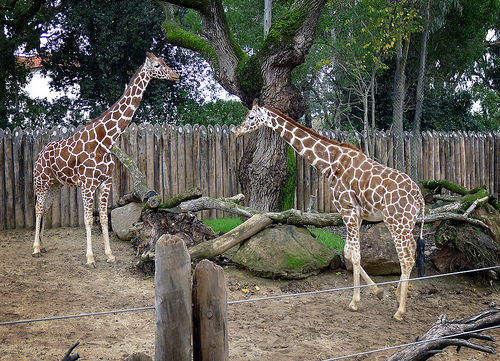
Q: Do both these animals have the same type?
A: Yes, all the animals are giraffes.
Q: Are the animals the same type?
A: Yes, all the animals are giraffes.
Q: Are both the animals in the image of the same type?
A: Yes, all the animals are giraffes.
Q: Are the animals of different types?
A: No, all the animals are giraffes.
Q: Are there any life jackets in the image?
A: No, there are no life jackets.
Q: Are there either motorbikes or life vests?
A: No, there are no life vests or motorbikes.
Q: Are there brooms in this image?
A: No, there are no brooms.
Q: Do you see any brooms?
A: No, there are no brooms.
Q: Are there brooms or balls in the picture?
A: No, there are no brooms or balls.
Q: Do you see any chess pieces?
A: No, there are no chess pieces.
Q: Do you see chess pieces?
A: No, there are no chess pieces.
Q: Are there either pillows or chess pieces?
A: No, there are no chess pieces or pillows.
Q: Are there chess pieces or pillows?
A: No, there are no chess pieces or pillows.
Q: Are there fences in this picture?
A: Yes, there is a fence.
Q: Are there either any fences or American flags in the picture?
A: Yes, there is a fence.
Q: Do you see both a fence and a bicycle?
A: No, there is a fence but no bicycles.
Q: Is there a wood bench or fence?
A: Yes, there is a wood fence.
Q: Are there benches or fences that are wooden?
A: Yes, the fence is wooden.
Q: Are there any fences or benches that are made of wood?
A: Yes, the fence is made of wood.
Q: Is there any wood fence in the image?
A: Yes, there is a fence that is made of wood.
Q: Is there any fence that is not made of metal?
A: Yes, there is a fence that is made of wood.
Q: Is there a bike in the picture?
A: No, there are no bikes.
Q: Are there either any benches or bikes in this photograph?
A: No, there are no bikes or benches.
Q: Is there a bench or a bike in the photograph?
A: No, there are no bikes or benches.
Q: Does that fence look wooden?
A: Yes, the fence is wooden.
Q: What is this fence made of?
A: The fence is made of wood.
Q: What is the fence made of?
A: The fence is made of wood.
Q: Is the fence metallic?
A: No, the fence is wooden.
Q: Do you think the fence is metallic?
A: No, the fence is wooden.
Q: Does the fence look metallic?
A: No, the fence is wooden.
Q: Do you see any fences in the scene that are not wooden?
A: No, there is a fence but it is wooden.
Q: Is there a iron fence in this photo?
A: No, there is a fence but it is made of wood.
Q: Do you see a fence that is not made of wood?
A: No, there is a fence but it is made of wood.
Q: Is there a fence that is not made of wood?
A: No, there is a fence but it is made of wood.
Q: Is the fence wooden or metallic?
A: The fence is wooden.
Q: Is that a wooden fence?
A: Yes, that is a wooden fence.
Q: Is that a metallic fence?
A: No, that is a wooden fence.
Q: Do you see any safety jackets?
A: No, there are no safety jackets.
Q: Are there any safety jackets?
A: No, there are no safety jackets.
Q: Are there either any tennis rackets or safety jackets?
A: No, there are no safety jackets or tennis rackets.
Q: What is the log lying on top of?
A: The log is lying on top of the rock.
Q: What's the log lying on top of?
A: The log is lying on top of the rock.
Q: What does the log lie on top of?
A: The log lies on top of the rock.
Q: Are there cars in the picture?
A: No, there are no cars.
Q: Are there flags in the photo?
A: No, there are no flags.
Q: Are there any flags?
A: No, there are no flags.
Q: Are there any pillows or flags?
A: No, there are no flags or pillows.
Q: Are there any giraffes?
A: Yes, there is a giraffe.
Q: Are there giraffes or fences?
A: Yes, there is a giraffe.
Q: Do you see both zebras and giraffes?
A: No, there is a giraffe but no zebras.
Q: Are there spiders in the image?
A: No, there are no spiders.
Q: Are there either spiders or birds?
A: No, there are no spiders or birds.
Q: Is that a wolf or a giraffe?
A: That is a giraffe.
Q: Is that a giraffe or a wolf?
A: That is a giraffe.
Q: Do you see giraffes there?
A: Yes, there is a giraffe.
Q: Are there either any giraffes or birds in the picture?
A: Yes, there is a giraffe.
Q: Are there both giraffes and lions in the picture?
A: No, there is a giraffe but no lions.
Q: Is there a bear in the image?
A: No, there are no bears.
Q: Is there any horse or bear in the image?
A: No, there are no bears or horses.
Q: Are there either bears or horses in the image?
A: No, there are no bears or horses.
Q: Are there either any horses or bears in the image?
A: No, there are no bears or horses.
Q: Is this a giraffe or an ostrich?
A: This is a giraffe.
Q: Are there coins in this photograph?
A: No, there are no coins.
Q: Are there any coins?
A: No, there are no coins.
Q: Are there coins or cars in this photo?
A: No, there are no coins or cars.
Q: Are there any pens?
A: No, there are no pens.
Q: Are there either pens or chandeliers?
A: No, there are no pens or chandeliers.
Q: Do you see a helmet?
A: No, there are no helmets.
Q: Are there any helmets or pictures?
A: No, there are no helmets or pictures.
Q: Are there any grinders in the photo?
A: No, there are no grinders.